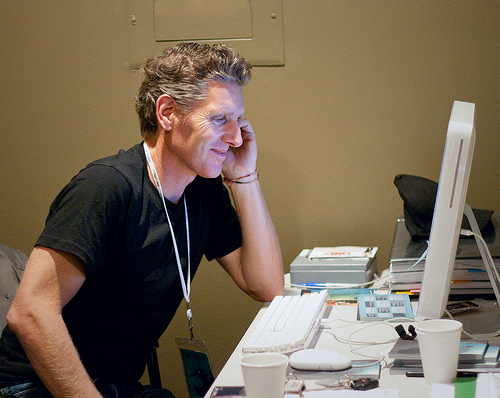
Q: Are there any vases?
A: No, there are no vases.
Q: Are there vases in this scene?
A: No, there are no vases.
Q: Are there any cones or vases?
A: No, there are no vases or cones.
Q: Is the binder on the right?
A: Yes, the binder is on the right of the image.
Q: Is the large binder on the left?
A: No, the binder is on the right of the image.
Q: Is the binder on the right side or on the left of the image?
A: The binder is on the right of the image.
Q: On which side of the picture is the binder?
A: The binder is on the right of the image.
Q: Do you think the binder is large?
A: Yes, the binder is large.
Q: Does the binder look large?
A: Yes, the binder is large.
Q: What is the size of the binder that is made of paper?
A: The binder is large.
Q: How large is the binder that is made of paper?
A: The binder is large.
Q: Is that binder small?
A: No, the binder is large.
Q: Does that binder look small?
A: No, the binder is large.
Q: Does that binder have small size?
A: No, the binder is large.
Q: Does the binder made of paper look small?
A: No, the binder is large.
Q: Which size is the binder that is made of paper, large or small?
A: The binder is large.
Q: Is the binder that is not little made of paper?
A: Yes, the binder is made of paper.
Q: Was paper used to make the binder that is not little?
A: Yes, the binder is made of paper.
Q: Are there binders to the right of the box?
A: Yes, there is a binder to the right of the box.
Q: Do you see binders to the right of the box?
A: Yes, there is a binder to the right of the box.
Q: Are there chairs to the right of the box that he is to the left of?
A: No, there is a binder to the right of the box.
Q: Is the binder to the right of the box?
A: Yes, the binder is to the right of the box.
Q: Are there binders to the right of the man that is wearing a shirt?
A: Yes, there is a binder to the right of the man.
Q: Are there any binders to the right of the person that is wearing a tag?
A: Yes, there is a binder to the right of the man.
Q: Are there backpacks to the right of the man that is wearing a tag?
A: No, there is a binder to the right of the man.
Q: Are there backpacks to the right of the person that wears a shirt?
A: No, there is a binder to the right of the man.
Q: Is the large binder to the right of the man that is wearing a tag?
A: Yes, the binder is to the right of the man.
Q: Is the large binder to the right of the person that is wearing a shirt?
A: Yes, the binder is to the right of the man.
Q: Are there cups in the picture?
A: Yes, there is a cup.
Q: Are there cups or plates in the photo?
A: Yes, there is a cup.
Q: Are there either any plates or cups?
A: Yes, there is a cup.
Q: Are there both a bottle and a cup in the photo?
A: No, there is a cup but no bottles.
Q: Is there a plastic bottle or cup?
A: Yes, there is a plastic cup.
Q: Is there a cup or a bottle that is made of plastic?
A: Yes, the cup is made of plastic.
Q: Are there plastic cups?
A: Yes, there is a cup that is made of plastic.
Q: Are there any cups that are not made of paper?
A: Yes, there is a cup that is made of plastic.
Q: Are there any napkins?
A: No, there are no napkins.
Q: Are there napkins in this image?
A: No, there are no napkins.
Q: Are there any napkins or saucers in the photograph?
A: No, there are no napkins or saucers.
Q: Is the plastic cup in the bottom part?
A: Yes, the cup is in the bottom of the image.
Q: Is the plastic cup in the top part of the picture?
A: No, the cup is in the bottom of the image.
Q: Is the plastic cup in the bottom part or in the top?
A: The cup is in the bottom of the image.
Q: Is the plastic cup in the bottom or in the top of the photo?
A: The cup is in the bottom of the image.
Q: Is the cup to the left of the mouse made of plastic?
A: Yes, the cup is made of plastic.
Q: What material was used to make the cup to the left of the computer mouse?
A: The cup is made of plastic.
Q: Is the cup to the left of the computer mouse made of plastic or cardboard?
A: The cup is made of plastic.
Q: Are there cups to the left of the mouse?
A: Yes, there is a cup to the left of the mouse.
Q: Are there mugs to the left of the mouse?
A: No, there is a cup to the left of the mouse.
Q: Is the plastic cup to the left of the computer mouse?
A: Yes, the cup is to the left of the computer mouse.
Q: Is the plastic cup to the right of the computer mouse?
A: No, the cup is to the left of the computer mouse.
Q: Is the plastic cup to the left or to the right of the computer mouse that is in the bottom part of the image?
A: The cup is to the left of the mouse.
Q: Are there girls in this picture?
A: No, there are no girls.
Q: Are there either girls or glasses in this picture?
A: No, there are no girls or glasses.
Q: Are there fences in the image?
A: No, there are no fences.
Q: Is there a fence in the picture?
A: No, there are no fences.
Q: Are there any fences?
A: No, there are no fences.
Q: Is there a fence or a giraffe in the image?
A: No, there are no fences or giraffes.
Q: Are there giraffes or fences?
A: No, there are no fences or giraffes.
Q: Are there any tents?
A: No, there are no tents.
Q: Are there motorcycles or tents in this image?
A: No, there are no tents or motorcycles.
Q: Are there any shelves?
A: No, there are no shelves.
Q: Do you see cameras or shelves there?
A: No, there are no shelves or cameras.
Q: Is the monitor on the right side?
A: Yes, the monitor is on the right of the image.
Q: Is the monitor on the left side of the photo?
A: No, the monitor is on the right of the image.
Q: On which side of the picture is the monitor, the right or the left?
A: The monitor is on the right of the image.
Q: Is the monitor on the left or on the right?
A: The monitor is on the right of the image.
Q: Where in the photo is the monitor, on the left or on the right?
A: The monitor is on the right of the image.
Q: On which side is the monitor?
A: The monitor is on the right of the image.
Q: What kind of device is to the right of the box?
A: The device is a monitor.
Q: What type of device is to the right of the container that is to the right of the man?
A: The device is a monitor.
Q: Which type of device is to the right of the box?
A: The device is a monitor.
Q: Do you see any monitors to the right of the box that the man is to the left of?
A: Yes, there is a monitor to the right of the box.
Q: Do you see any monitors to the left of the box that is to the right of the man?
A: No, the monitor is to the right of the box.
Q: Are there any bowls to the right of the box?
A: No, there is a monitor to the right of the box.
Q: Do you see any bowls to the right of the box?
A: No, there is a monitor to the right of the box.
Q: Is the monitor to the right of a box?
A: Yes, the monitor is to the right of a box.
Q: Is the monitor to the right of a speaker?
A: No, the monitor is to the right of a box.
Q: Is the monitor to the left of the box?
A: No, the monitor is to the right of the box.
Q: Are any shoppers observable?
A: No, there are no shoppers.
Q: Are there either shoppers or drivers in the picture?
A: No, there are no shoppers or drivers.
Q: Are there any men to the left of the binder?
A: Yes, there is a man to the left of the binder.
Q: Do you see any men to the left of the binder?
A: Yes, there is a man to the left of the binder.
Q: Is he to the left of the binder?
A: Yes, the man is to the left of the binder.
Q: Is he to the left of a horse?
A: No, the man is to the left of the binder.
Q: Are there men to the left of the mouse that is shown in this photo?
A: Yes, there is a man to the left of the mouse.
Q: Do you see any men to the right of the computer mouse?
A: No, the man is to the left of the computer mouse.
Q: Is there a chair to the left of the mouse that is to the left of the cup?
A: No, there is a man to the left of the mouse.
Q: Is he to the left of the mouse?
A: Yes, the man is to the left of the mouse.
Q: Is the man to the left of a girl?
A: No, the man is to the left of the mouse.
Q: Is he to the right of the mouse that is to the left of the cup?
A: No, the man is to the left of the computer mouse.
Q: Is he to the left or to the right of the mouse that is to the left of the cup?
A: The man is to the left of the mouse.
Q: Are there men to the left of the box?
A: Yes, there is a man to the left of the box.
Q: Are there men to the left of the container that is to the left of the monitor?
A: Yes, there is a man to the left of the box.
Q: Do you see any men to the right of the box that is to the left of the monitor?
A: No, the man is to the left of the box.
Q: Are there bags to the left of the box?
A: No, there is a man to the left of the box.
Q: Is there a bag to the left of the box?
A: No, there is a man to the left of the box.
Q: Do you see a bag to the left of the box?
A: No, there is a man to the left of the box.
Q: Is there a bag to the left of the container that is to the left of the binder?
A: No, there is a man to the left of the box.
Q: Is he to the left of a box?
A: Yes, the man is to the left of a box.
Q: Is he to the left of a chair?
A: No, the man is to the left of a box.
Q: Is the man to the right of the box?
A: No, the man is to the left of the box.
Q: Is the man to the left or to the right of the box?
A: The man is to the left of the box.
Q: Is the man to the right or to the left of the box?
A: The man is to the left of the box.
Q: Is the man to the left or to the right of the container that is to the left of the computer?
A: The man is to the left of the box.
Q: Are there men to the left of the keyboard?
A: Yes, there is a man to the left of the keyboard.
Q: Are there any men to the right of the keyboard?
A: No, the man is to the left of the keyboard.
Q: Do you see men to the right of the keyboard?
A: No, the man is to the left of the keyboard.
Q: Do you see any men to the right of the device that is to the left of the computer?
A: No, the man is to the left of the keyboard.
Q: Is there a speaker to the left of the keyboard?
A: No, there is a man to the left of the keyboard.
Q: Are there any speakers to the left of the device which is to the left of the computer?
A: No, there is a man to the left of the keyboard.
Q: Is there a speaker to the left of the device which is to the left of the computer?
A: No, there is a man to the left of the keyboard.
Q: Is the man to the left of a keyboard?
A: Yes, the man is to the left of a keyboard.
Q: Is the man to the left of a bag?
A: No, the man is to the left of a keyboard.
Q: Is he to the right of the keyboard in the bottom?
A: No, the man is to the left of the keyboard.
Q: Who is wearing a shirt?
A: The man is wearing a shirt.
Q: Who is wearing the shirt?
A: The man is wearing a shirt.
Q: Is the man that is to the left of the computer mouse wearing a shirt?
A: Yes, the man is wearing a shirt.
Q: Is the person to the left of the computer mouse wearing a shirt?
A: Yes, the man is wearing a shirt.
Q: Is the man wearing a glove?
A: No, the man is wearing a shirt.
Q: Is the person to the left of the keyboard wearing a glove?
A: No, the man is wearing a shirt.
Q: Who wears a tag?
A: The man wears a tag.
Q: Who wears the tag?
A: The man wears a tag.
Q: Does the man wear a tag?
A: Yes, the man wears a tag.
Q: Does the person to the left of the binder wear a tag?
A: Yes, the man wears a tag.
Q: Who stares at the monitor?
A: The man stares at the monitor.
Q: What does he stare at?
A: The man stares at the monitor.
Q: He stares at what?
A: The man stares at the monitor.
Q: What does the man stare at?
A: The man stares at the monitor.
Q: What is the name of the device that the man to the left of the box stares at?
A: The device is a monitor.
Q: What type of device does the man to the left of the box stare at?
A: The man stares at the monitor.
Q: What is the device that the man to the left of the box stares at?
A: The device is a monitor.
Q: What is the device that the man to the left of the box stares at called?
A: The device is a monitor.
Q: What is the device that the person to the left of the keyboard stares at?
A: The device is a monitor.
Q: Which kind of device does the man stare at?
A: The man stares at the monitor.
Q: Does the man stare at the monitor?
A: Yes, the man stares at the monitor.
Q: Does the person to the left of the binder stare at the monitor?
A: Yes, the man stares at the monitor.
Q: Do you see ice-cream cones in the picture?
A: No, there are no ice-cream cones.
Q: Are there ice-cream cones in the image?
A: No, there are no ice-cream cones.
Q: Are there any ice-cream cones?
A: No, there are no ice-cream cones.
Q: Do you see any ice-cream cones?
A: No, there are no ice-cream cones.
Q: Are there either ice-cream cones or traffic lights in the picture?
A: No, there are no ice-cream cones or traffic lights.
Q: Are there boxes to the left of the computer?
A: Yes, there is a box to the left of the computer.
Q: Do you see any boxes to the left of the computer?
A: Yes, there is a box to the left of the computer.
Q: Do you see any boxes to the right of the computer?
A: No, the box is to the left of the computer.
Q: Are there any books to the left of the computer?
A: No, there is a box to the left of the computer.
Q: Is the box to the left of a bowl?
A: No, the box is to the left of a computer.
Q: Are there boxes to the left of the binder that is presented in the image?
A: Yes, there is a box to the left of the binder.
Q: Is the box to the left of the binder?
A: Yes, the box is to the left of the binder.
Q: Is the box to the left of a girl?
A: No, the box is to the left of the binder.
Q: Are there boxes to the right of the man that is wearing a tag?
A: Yes, there is a box to the right of the man.